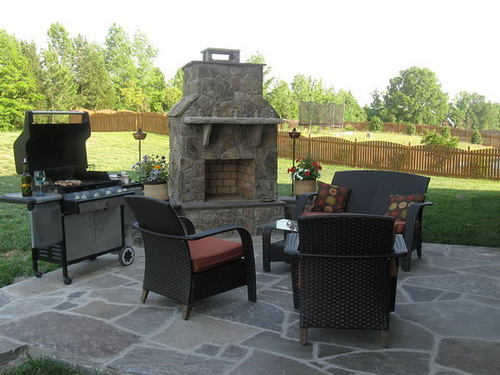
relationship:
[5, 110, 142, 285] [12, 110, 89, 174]
barbeque grill with lid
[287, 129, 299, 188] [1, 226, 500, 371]
light near porch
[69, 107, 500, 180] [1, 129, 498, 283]
fence lining yard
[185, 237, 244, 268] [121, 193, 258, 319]
cushion of a chairs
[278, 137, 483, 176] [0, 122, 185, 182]
fence of yard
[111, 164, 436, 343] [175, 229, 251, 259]
chairs with cushions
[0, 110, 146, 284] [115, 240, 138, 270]
barbeque grill with wheels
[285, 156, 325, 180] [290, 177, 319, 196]
flowers in pot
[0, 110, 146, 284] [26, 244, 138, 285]
barbeque grill with wheels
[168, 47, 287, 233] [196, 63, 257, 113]
fire place made of rocks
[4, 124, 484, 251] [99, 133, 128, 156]
yard of grass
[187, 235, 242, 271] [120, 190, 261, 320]
cushion on chair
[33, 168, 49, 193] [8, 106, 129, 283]
wine glass on grill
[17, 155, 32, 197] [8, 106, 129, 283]
bottle on grill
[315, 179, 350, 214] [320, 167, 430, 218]
pillow on bench